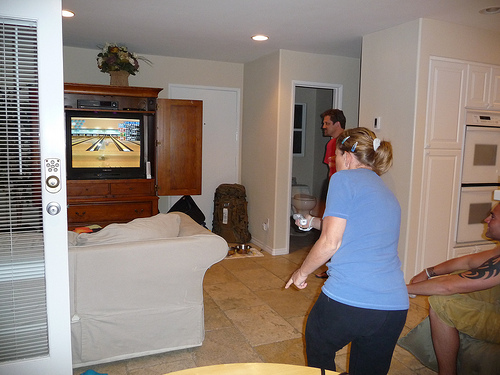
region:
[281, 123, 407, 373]
A woman holding a Wii controller and looking at a television.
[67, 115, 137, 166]
A bowling alley on the television screen.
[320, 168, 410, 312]
The woman is wearing a blue top.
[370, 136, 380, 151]
White scrunchie in the woman's hair.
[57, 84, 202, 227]
Television set in a large wooden stand.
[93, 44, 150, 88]
A basket of flowers on top of the television stand.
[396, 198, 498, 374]
A man behind the woman with a tattoo on his arm.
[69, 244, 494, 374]
Tan ceramic tile on the floor.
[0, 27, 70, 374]
A glass door with mini blinds over the glass.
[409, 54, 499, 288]
White kitchen cupboards.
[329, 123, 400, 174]
Blonde hair tied with with band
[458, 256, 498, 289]
Green tattoo on mans arm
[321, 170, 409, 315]
Lady with light blue shirt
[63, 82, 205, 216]
Television in brown wood cabinet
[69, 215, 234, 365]
Back side of white couch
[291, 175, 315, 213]
White toilet in bathroom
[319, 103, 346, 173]
Man with red shirt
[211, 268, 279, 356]
Brown square tile floor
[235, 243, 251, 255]
Silver bowl on floor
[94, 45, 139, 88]
Basket of flowers on top of cabinet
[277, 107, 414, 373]
Woman playing wii game.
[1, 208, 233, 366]
Tan couch in the room.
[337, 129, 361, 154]
Barretts in the hair.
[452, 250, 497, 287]
Tattoo on the arm.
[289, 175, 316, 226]
White toilet in the background.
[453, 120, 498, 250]
Ovens in the wall.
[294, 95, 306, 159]
window in the wall.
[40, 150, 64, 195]
Lock on the door.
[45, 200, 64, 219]
door knob on the door.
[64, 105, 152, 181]
Television in the cabinet.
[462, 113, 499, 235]
stoves on the wall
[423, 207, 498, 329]
a man sitting down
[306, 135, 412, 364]
a lady in a blue shirt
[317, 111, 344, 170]
a man in a red shirt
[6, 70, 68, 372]
the door on the building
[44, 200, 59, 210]
a silver door knob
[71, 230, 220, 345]
a white couch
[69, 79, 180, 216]
a wooden dresser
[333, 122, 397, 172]
The woman's hair is blonde.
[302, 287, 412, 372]
The woman has dark pants.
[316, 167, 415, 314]
The woman has on a blue shirt.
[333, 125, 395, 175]
The woman has her hair in a pony tail.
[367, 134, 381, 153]
The woman's hair tie is white.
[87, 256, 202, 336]
The couch is white in color.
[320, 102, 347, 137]
The man's hair is brown.